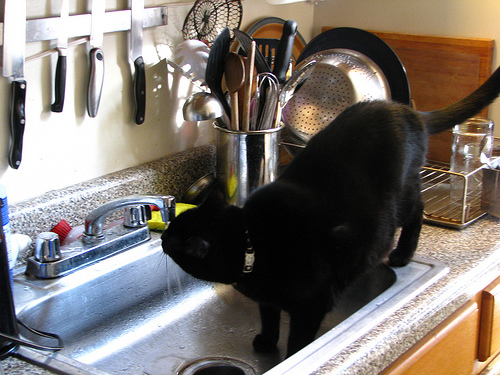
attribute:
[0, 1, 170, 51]
bar — magnetic 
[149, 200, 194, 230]
sponge — yellow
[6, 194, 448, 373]
sink — large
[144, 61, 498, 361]
cat — black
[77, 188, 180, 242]
faucet — metal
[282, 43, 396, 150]
colander — metal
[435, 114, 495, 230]
glass — clean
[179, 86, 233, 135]
ladle — metal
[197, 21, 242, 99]
spaghetti server — plastic